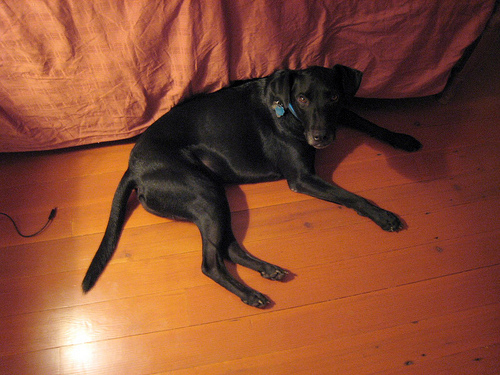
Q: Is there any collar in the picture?
A: Yes, there is a collar.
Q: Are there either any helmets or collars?
A: Yes, there is a collar.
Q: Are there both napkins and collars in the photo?
A: No, there is a collar but no napkins.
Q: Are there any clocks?
A: No, there are no clocks.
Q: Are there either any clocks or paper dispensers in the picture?
A: No, there are no clocks or paper dispensers.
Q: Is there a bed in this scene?
A: Yes, there is a bed.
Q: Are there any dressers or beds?
A: Yes, there is a bed.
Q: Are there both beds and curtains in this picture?
A: No, there is a bed but no curtains.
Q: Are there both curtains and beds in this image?
A: No, there is a bed but no curtains.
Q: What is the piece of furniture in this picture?
A: The piece of furniture is a bed.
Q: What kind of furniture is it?
A: The piece of furniture is a bed.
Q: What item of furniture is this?
A: This is a bed.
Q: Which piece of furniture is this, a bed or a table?
A: This is a bed.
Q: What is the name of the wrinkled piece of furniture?
A: The piece of furniture is a bed.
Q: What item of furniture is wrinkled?
A: The piece of furniture is a bed.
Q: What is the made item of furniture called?
A: The piece of furniture is a bed.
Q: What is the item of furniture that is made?
A: The piece of furniture is a bed.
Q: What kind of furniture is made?
A: The furniture is a bed.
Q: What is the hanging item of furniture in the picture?
A: The piece of furniture is a bed.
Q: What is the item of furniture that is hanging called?
A: The piece of furniture is a bed.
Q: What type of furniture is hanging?
A: The furniture is a bed.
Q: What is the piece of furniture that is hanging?
A: The piece of furniture is a bed.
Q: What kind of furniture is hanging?
A: The furniture is a bed.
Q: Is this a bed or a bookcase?
A: This is a bed.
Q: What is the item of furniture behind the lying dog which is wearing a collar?
A: The piece of furniture is a bed.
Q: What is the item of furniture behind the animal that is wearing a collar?
A: The piece of furniture is a bed.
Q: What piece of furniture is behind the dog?
A: The piece of furniture is a bed.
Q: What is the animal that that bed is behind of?
A: The animal is a dog.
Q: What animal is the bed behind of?
A: The bed is behind the dog.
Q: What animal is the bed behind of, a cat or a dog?
A: The bed is behind a dog.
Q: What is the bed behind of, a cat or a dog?
A: The bed is behind a dog.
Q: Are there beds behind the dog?
A: Yes, there is a bed behind the dog.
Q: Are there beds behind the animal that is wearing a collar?
A: Yes, there is a bed behind the dog.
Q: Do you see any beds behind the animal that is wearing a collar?
A: Yes, there is a bed behind the dog.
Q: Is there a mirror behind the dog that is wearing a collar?
A: No, there is a bed behind the dog.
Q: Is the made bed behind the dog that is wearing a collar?
A: Yes, the bed is behind the dog.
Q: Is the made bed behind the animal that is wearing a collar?
A: Yes, the bed is behind the dog.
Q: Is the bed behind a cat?
A: No, the bed is behind the dog.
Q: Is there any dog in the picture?
A: Yes, there is a dog.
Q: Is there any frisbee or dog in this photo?
A: Yes, there is a dog.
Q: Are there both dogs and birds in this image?
A: No, there is a dog but no birds.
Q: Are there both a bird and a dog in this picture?
A: No, there is a dog but no birds.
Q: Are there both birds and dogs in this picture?
A: No, there is a dog but no birds.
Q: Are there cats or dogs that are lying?
A: Yes, the dog is lying.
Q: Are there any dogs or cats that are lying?
A: Yes, the dog is lying.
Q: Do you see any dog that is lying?
A: Yes, there is a dog that is lying.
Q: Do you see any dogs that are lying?
A: Yes, there is a dog that is lying.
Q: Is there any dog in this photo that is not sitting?
A: Yes, there is a dog that is lying.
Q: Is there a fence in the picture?
A: No, there are no fences.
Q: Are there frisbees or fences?
A: No, there are no fences or frisbees.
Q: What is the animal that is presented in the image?
A: The animal is a dog.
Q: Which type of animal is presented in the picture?
A: The animal is a dog.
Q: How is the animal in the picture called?
A: The animal is a dog.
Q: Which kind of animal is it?
A: The animal is a dog.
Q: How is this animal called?
A: This is a dog.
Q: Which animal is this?
A: This is a dog.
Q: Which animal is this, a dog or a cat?
A: This is a dog.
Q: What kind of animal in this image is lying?
A: The animal is a dog.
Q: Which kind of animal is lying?
A: The animal is a dog.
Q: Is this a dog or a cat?
A: This is a dog.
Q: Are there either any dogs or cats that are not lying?
A: No, there is a dog but it is lying.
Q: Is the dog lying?
A: Yes, the dog is lying.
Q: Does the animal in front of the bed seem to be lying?
A: Yes, the dog is lying.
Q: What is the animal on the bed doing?
A: The dog is lying.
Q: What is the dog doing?
A: The dog is lying.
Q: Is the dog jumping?
A: No, the dog is lying.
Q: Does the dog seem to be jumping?
A: No, the dog is lying.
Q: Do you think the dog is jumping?
A: No, the dog is lying.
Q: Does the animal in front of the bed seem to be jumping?
A: No, the dog is lying.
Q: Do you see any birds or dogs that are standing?
A: No, there is a dog but it is lying.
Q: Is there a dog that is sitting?
A: No, there is a dog but it is lying.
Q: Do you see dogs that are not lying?
A: No, there is a dog but it is lying.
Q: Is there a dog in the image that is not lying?
A: No, there is a dog but it is lying.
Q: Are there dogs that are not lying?
A: No, there is a dog but it is lying.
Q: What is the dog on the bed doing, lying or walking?
A: The dog is lying.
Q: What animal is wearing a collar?
A: The animal is a dog.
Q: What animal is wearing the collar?
A: The animal is a dog.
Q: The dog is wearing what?
A: The dog is wearing a collar.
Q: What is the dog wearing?
A: The dog is wearing a collar.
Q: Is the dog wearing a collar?
A: Yes, the dog is wearing a collar.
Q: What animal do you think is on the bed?
A: The dog is on the bed.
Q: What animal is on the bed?
A: The dog is on the bed.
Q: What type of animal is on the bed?
A: The animal is a dog.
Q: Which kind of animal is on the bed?
A: The animal is a dog.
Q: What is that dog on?
A: The dog is on the bed.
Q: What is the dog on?
A: The dog is on the bed.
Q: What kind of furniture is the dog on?
A: The dog is on the bed.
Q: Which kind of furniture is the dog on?
A: The dog is on the bed.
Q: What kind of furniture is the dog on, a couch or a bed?
A: The dog is on a bed.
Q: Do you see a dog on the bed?
A: Yes, there is a dog on the bed.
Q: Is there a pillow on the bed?
A: No, there is a dog on the bed.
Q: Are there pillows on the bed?
A: No, there is a dog on the bed.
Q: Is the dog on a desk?
A: No, the dog is on the bed.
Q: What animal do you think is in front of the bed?
A: The dog is in front of the bed.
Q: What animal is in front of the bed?
A: The dog is in front of the bed.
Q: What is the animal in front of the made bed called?
A: The animal is a dog.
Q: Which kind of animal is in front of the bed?
A: The animal is a dog.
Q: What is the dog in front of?
A: The dog is in front of the bed.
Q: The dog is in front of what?
A: The dog is in front of the bed.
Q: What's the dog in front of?
A: The dog is in front of the bed.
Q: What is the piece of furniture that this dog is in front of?
A: The piece of furniture is a bed.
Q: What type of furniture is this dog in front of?
A: The dog is in front of the bed.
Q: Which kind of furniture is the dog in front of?
A: The dog is in front of the bed.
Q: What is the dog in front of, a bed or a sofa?
A: The dog is in front of a bed.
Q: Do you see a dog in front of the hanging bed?
A: Yes, there is a dog in front of the bed.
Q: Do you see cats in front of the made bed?
A: No, there is a dog in front of the bed.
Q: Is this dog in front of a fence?
A: No, the dog is in front of the bed.